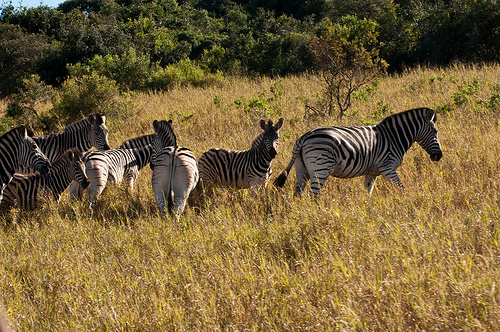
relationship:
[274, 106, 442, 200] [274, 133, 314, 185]
zebra has a tail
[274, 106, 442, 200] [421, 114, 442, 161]
zebra has a face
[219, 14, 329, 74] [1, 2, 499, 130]
bushes are in background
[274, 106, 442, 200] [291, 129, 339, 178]
zebra has a back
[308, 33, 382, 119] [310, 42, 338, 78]
tree has a branch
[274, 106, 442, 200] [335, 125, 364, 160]
zebra has a stripe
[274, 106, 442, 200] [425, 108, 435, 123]
zebra has an ear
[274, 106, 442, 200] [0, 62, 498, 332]
zebra are in grass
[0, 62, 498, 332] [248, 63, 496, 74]
grass has a shadow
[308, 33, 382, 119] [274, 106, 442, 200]
tree behind zebra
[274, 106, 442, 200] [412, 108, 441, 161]
zebra has a head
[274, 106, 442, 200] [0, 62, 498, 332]
zebra in a grass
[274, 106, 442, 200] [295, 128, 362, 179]
zebra has a back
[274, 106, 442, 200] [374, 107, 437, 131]
zebra has a mane